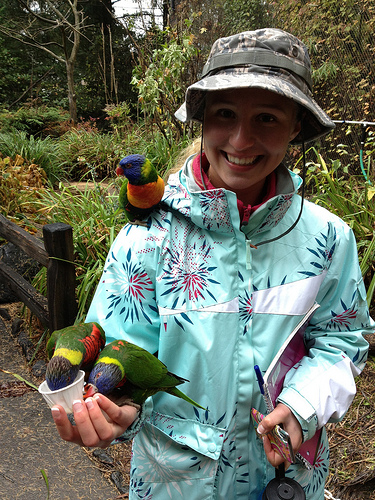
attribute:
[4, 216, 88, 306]
fence — wooden, large, wide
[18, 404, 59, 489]
trail — wide, large, stone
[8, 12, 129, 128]
tree — large, grey, barren